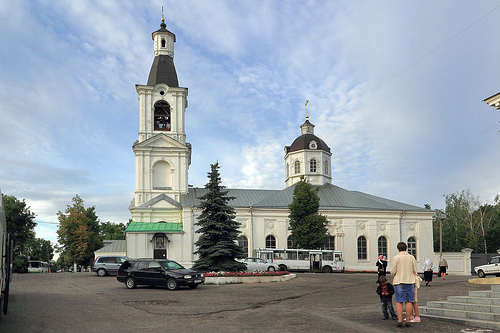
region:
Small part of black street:
[78, 311, 97, 324]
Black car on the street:
[126, 260, 189, 284]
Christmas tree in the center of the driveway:
[193, 170, 239, 274]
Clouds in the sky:
[249, 12, 288, 62]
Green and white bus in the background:
[26, 257, 46, 274]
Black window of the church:
[353, 235, 369, 263]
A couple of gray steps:
[436, 297, 494, 317]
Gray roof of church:
[343, 189, 376, 204]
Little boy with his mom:
[375, 235, 424, 320]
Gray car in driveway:
[247, 257, 272, 269]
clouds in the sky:
[212, 41, 280, 102]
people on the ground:
[345, 228, 446, 328]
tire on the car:
[157, 275, 184, 299]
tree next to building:
[190, 172, 268, 256]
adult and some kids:
[370, 235, 442, 320]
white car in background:
[236, 249, 291, 277]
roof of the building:
[233, 176, 290, 210]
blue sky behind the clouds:
[216, 36, 293, 94]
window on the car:
[158, 256, 185, 283]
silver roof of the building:
[241, 181, 282, 203]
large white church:
[137, 5, 466, 277]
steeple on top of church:
[155, 2, 167, 24]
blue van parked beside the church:
[92, 250, 125, 275]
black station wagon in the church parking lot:
[115, 250, 200, 290]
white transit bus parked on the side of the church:
[253, 245, 345, 277]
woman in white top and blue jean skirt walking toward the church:
[387, 238, 423, 325]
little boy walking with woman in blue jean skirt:
[372, 271, 396, 316]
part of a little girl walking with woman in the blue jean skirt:
[408, 265, 421, 323]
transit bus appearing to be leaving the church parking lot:
[24, 254, 49, 274]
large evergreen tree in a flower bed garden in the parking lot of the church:
[186, 160, 244, 273]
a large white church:
[96, 25, 473, 277]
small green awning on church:
[125, 219, 183, 233]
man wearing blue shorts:
[389, 241, 415, 327]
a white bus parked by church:
[251, 247, 346, 272]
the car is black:
[116, 257, 205, 290]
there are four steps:
[408, 282, 498, 331]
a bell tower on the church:
[129, 27, 191, 222]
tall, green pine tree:
[193, 159, 246, 269]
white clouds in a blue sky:
[243, 27, 382, 98]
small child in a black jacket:
[377, 272, 399, 318]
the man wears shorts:
[385, 230, 420, 320]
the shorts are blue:
[390, 280, 415, 306]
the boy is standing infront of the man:
[370, 272, 395, 319]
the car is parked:
[112, 254, 215, 301]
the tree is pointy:
[188, 152, 247, 267]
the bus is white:
[262, 247, 349, 273]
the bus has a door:
[258, 245, 349, 272]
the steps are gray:
[462, 290, 488, 323]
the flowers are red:
[202, 268, 264, 279]